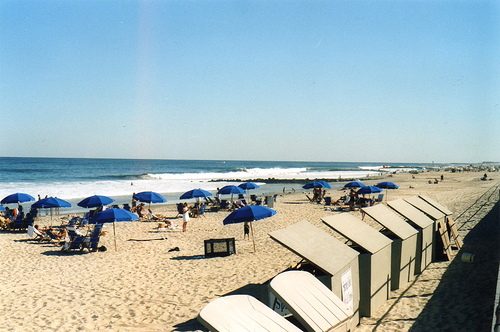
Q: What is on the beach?
A: Sand.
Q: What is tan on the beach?
A: Sand.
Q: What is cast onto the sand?
A: Shadow of boardwalk.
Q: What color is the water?
A: Its blue.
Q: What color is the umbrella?
A: They are blue.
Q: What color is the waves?
A: They are white.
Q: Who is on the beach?
A: A lot of people.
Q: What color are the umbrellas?
A: Blue.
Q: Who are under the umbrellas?
A: Beach goers.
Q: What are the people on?
A: Sand.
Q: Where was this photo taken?
A: A beach.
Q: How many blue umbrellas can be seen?
A: Thirteen.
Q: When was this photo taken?
A: Daytime.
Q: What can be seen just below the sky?
A: An ocean.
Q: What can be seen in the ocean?
A: Waves.